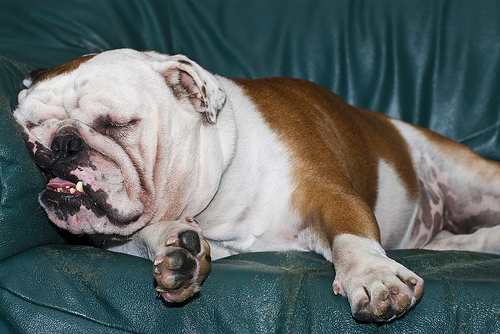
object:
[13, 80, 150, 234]
dog face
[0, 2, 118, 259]
couch arm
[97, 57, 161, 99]
hair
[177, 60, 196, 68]
spots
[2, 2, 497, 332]
couch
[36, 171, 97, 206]
mouth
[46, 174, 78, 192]
tongue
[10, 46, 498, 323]
dog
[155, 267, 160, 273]
toe nails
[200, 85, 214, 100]
spots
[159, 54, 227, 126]
ear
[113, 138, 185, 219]
wrinkles